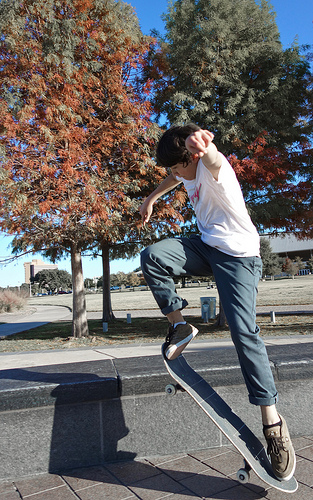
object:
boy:
[133, 120, 297, 482]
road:
[0, 330, 312, 462]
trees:
[1, 2, 167, 340]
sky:
[0, 2, 312, 256]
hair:
[153, 124, 204, 169]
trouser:
[139, 230, 278, 409]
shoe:
[163, 318, 197, 363]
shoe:
[256, 408, 296, 483]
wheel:
[162, 382, 177, 403]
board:
[159, 338, 298, 496]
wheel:
[233, 463, 249, 486]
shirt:
[175, 157, 260, 259]